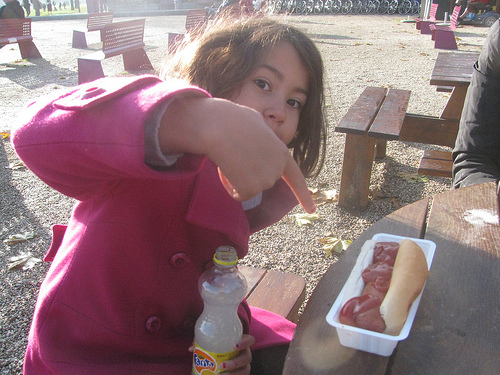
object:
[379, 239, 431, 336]
bun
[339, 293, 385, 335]
ketchup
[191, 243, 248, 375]
bottle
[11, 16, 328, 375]
girl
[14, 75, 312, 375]
coat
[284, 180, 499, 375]
table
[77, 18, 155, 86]
bench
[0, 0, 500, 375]
ground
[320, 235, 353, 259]
leaves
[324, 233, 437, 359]
container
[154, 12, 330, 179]
hair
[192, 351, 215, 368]
fanta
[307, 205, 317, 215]
fingernail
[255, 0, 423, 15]
row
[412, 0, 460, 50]
pair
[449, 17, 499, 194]
person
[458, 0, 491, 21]
person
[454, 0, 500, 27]
scooter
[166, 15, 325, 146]
head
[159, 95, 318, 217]
hand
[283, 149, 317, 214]
finger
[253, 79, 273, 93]
eye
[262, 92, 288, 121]
nose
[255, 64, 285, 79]
eyebrow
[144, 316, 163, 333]
button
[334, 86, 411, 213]
seat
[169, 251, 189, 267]
button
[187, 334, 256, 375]
hand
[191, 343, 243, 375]
label